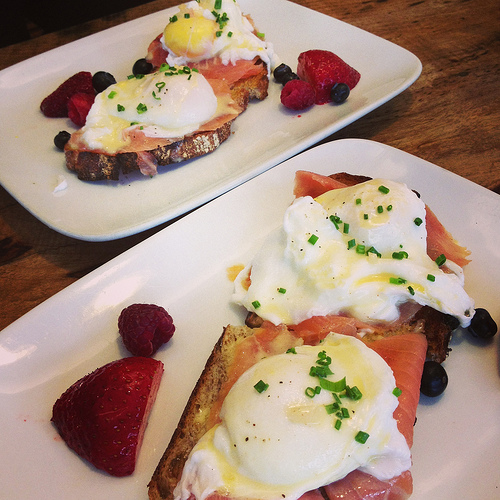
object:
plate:
[0, 0, 423, 242]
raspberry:
[118, 304, 176, 357]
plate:
[1, 137, 499, 499]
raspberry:
[280, 79, 315, 110]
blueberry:
[330, 83, 350, 104]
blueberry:
[421, 361, 449, 397]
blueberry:
[92, 71, 116, 92]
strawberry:
[52, 355, 164, 478]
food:
[40, 0, 362, 183]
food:
[53, 170, 497, 498]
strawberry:
[298, 49, 362, 103]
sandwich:
[145, 170, 473, 499]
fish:
[208, 314, 429, 500]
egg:
[172, 331, 410, 500]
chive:
[254, 379, 268, 394]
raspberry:
[68, 93, 95, 126]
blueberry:
[54, 131, 72, 150]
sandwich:
[63, 0, 279, 182]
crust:
[64, 121, 230, 182]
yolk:
[164, 11, 220, 55]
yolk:
[101, 115, 130, 151]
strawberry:
[40, 71, 95, 117]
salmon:
[148, 31, 266, 96]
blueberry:
[132, 58, 153, 76]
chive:
[156, 82, 167, 92]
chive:
[308, 234, 319, 246]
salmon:
[293, 169, 474, 328]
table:
[0, 1, 500, 332]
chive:
[212, 10, 218, 17]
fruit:
[50, 302, 176, 476]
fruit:
[273, 50, 361, 110]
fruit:
[39, 70, 117, 125]